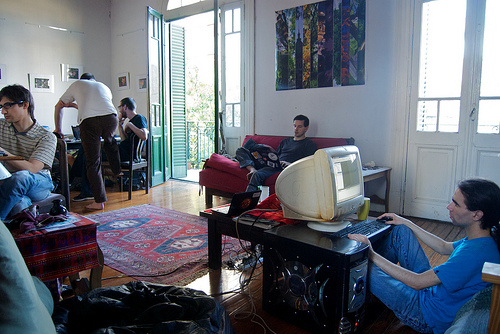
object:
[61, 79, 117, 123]
white shirt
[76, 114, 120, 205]
pants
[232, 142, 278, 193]
pants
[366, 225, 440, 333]
pants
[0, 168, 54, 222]
pants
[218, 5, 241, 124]
window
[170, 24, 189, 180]
door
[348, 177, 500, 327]
man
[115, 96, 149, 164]
man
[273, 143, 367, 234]
monitor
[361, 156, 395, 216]
table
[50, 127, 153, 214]
table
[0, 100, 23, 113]
glasses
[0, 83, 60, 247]
man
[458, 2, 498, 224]
white door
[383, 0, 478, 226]
white door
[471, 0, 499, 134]
window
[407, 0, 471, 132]
window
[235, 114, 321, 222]
man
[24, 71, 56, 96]
picture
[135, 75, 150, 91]
picture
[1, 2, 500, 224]
wall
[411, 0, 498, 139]
windows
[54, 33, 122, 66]
wall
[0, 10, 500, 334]
room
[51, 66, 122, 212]
man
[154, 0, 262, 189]
door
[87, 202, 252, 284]
rug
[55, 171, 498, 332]
floor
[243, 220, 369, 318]
tower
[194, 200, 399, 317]
table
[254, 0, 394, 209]
wall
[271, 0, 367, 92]
collage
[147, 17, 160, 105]
window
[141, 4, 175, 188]
door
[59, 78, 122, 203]
body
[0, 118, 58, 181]
shirt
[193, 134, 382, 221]
couch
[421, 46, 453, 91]
sunlight